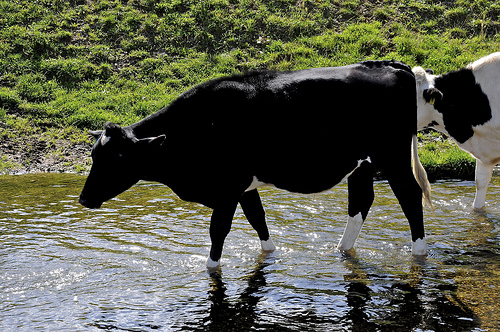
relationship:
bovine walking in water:
[411, 49, 500, 212] [5, 176, 486, 329]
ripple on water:
[36, 219, 165, 287] [36, 232, 151, 301]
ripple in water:
[0, 171, 500, 332] [0, 209, 201, 330]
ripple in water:
[0, 171, 500, 332] [302, 237, 434, 295]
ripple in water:
[0, 171, 500, 332] [5, 176, 486, 329]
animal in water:
[77, 57, 439, 270] [78, 210, 485, 317]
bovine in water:
[411, 49, 500, 212] [78, 210, 485, 317]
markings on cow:
[210, 145, 430, 269] [39, 41, 484, 269]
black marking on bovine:
[435, 61, 494, 143] [411, 49, 500, 212]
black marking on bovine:
[422, 66, 494, 146] [411, 49, 500, 212]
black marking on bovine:
[419, 120, 438, 130] [411, 49, 500, 212]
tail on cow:
[394, 57, 433, 198] [53, 24, 440, 294]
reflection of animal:
[191, 259, 487, 330] [77, 54, 433, 271]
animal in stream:
[77, 54, 433, 271] [2, 172, 498, 329]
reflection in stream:
[191, 259, 487, 330] [2, 172, 498, 329]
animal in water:
[77, 57, 439, 270] [5, 176, 486, 329]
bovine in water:
[411, 51, 499, 211] [5, 176, 486, 329]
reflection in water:
[0, 204, 500, 332] [5, 176, 486, 329]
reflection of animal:
[0, 204, 500, 332] [77, 57, 439, 270]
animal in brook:
[77, 57, 439, 270] [10, 172, 493, 325]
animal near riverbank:
[77, 57, 439, 270] [1, 102, 498, 192]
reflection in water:
[191, 259, 487, 330] [5, 176, 486, 329]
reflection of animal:
[191, 259, 487, 330] [77, 57, 439, 270]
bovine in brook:
[411, 49, 500, 212] [10, 172, 493, 325]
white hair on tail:
[409, 134, 436, 213] [409, 78, 434, 212]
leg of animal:
[241, 183, 275, 255] [77, 57, 439, 270]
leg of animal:
[206, 207, 232, 266] [77, 57, 439, 270]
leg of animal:
[239, 184, 276, 251] [77, 57, 439, 270]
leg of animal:
[392, 164, 430, 256] [77, 57, 439, 270]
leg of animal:
[341, 181, 371, 251] [77, 57, 439, 270]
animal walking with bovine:
[77, 57, 439, 270] [411, 49, 500, 212]